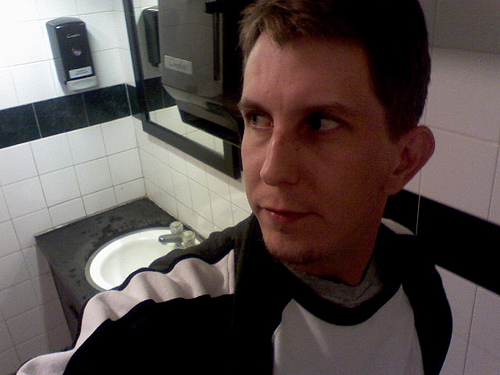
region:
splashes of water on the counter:
[79, 201, 146, 249]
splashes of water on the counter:
[79, 207, 154, 250]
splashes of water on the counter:
[85, 202, 138, 239]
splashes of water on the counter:
[63, 193, 128, 246]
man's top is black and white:
[140, 234, 432, 374]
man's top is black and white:
[162, 227, 402, 353]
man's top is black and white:
[150, 264, 451, 356]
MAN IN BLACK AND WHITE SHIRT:
[9, 4, 464, 374]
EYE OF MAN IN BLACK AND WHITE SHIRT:
[305, 110, 352, 133]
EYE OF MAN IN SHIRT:
[305, 113, 356, 137]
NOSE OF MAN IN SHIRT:
[256, 120, 298, 194]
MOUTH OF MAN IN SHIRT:
[251, 199, 327, 225]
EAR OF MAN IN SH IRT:
[391, 121, 447, 203]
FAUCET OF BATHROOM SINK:
[158, 223, 190, 247]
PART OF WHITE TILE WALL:
[68, 165, 149, 195]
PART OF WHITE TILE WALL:
[453, 48, 484, 135]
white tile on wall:
[97, 121, 136, 157]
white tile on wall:
[65, 123, 105, 164]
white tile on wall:
[30, 131, 74, 173]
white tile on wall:
[0, 139, 37, 182]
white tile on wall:
[105, 146, 146, 184]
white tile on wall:
[72, 156, 114, 198]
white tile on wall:
[36, 165, 80, 208]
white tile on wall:
[4, 179, 46, 216]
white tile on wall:
[110, 181, 148, 204]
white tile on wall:
[78, 185, 118, 212]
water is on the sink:
[67, 215, 163, 282]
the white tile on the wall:
[62, 152, 138, 182]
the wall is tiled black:
[36, 102, 88, 173]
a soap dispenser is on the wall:
[41, 5, 166, 132]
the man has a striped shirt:
[155, 268, 338, 368]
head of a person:
[193, 6, 445, 278]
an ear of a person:
[362, 105, 444, 195]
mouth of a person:
[240, 191, 358, 242]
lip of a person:
[257, 188, 321, 230]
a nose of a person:
[239, 155, 311, 202]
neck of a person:
[287, 205, 429, 307]